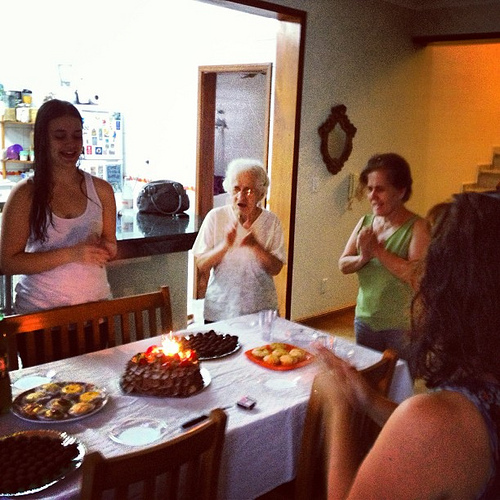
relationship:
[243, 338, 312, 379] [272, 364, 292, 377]
cookies on plate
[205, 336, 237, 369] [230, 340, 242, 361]
cookies on plate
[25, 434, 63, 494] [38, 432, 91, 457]
cookies on plate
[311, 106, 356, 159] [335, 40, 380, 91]
mirror on wall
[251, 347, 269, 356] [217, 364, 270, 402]
cookies on top of table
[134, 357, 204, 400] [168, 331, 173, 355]
cake has candle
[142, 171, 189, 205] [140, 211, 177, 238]
bag on counter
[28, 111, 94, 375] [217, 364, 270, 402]
girl by table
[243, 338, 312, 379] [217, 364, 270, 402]
cookies on table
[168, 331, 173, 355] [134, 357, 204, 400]
candle on cake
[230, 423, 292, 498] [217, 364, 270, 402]
tablecloth on table